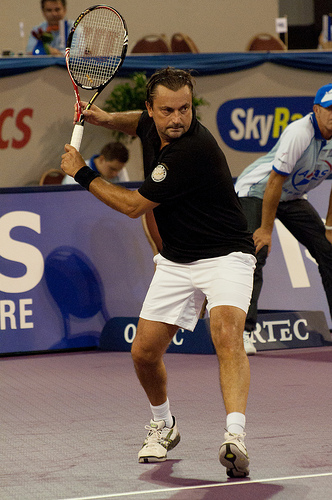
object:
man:
[60, 64, 258, 479]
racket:
[63, 3, 130, 150]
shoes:
[136, 414, 251, 480]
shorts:
[138, 250, 258, 331]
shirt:
[135, 107, 257, 265]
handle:
[68, 120, 86, 156]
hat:
[312, 84, 331, 109]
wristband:
[72, 164, 103, 193]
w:
[73, 24, 115, 64]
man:
[24, 0, 86, 59]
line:
[51, 469, 330, 500]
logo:
[150, 163, 167, 183]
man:
[233, 82, 332, 356]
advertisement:
[0, 90, 314, 158]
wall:
[1, 38, 329, 193]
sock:
[221, 410, 245, 437]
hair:
[145, 65, 195, 105]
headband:
[147, 72, 194, 88]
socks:
[146, 397, 246, 439]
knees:
[253, 239, 332, 264]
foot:
[217, 427, 250, 479]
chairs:
[131, 29, 287, 59]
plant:
[99, 71, 212, 141]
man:
[61, 140, 131, 188]